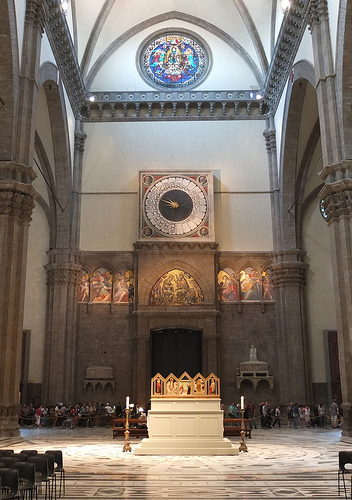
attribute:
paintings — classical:
[74, 263, 284, 304]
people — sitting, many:
[22, 398, 342, 429]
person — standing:
[260, 398, 269, 426]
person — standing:
[270, 401, 282, 427]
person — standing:
[302, 400, 312, 425]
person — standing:
[326, 397, 340, 430]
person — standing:
[227, 397, 237, 416]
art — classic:
[217, 267, 241, 303]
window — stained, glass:
[144, 31, 208, 89]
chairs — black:
[2, 447, 66, 498]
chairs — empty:
[15, 436, 84, 495]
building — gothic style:
[44, 71, 310, 462]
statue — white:
[244, 326, 276, 389]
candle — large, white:
[237, 395, 245, 411]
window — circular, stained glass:
[137, 33, 229, 94]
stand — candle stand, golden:
[238, 395, 249, 455]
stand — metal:
[118, 399, 142, 435]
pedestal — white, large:
[134, 396, 239, 460]